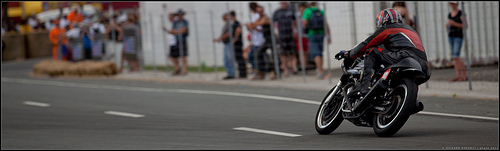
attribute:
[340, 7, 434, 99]
person —  red 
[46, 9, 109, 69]
people — orange clothing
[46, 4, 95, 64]
clothing — orange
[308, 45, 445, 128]
motorcycle — racing style 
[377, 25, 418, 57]
jacket — Black , red  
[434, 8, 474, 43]
tank top —  black tank 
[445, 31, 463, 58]
jeans — capri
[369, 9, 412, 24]
helmet — red patterned motorcycle , black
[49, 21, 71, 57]
jumpsuits —  orange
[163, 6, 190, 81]
people — standing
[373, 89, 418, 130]
tires — big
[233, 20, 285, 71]
person — standing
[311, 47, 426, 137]
motorcycle — black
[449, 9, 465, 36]
shirt — black 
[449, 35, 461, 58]
jeans — blue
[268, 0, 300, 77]
person —  red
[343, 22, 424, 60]
jacket — black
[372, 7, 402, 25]
helmet — black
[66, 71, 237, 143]
lines — white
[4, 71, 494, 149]
road — asphalt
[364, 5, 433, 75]
person —  leaning right 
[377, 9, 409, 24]
helmet — red , Black 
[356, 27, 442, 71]
jacket —  red,  black 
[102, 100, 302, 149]
strip — white dotted line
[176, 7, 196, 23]
hat — cowboy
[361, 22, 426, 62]
clothing — black, red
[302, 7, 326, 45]
shirt — green 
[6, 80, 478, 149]
street — empty